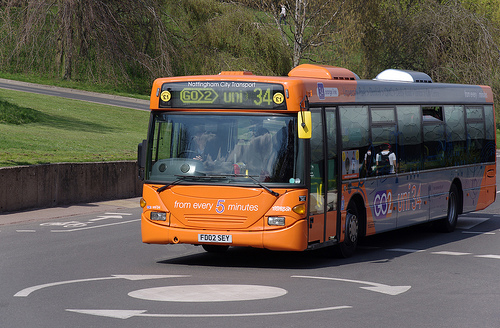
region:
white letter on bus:
[173, 198, 178, 210]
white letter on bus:
[177, 200, 184, 207]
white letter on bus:
[182, 200, 191, 209]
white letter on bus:
[191, 200, 198, 211]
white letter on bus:
[194, 199, 201, 208]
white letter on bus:
[200, 200, 206, 208]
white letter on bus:
[226, 200, 233, 211]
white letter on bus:
[373, 192, 383, 217]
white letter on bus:
[381, 192, 388, 215]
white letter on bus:
[252, 201, 259, 213]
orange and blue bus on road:
[129, 47, 499, 256]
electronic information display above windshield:
[115, 65, 295, 113]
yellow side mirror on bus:
[296, 92, 322, 138]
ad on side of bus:
[361, 158, 486, 243]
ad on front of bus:
[166, 190, 265, 217]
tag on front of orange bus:
[194, 224, 235, 251]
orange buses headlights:
[145, 197, 291, 232]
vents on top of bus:
[276, 46, 441, 88]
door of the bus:
[299, 96, 356, 249]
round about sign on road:
[24, 219, 421, 326]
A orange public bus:
[121, 49, 499, 266]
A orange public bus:
[133, 61, 498, 270]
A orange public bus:
[125, 54, 499, 269]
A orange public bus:
[123, 51, 494, 271]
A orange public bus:
[128, 59, 497, 261]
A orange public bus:
[131, 57, 499, 267]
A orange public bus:
[134, 60, 497, 260]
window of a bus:
[139, 105, 305, 195]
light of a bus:
[132, 190, 172, 241]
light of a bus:
[266, 205, 298, 238]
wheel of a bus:
[335, 195, 369, 253]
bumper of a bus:
[119, 180, 319, 260]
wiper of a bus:
[139, 163, 201, 210]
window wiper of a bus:
[238, 161, 311, 207]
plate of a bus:
[196, 225, 229, 247]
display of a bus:
[152, 81, 279, 113]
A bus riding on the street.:
[124, 58, 471, 256]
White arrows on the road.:
[301, 266, 411, 310]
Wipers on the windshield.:
[161, 167, 283, 197]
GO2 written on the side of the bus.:
[361, 174, 407, 222]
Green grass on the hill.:
[10, 89, 135, 146]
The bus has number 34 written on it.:
[244, 90, 279, 117]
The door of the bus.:
[300, 117, 346, 253]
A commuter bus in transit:
[136, 64, 497, 256]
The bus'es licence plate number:
[200, 233, 230, 244]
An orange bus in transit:
[135, 68, 497, 252]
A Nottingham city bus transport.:
[0, 0, 498, 326]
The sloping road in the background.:
[0, 79, 149, 121]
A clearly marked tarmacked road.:
[1, 154, 498, 326]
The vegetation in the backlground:
[1, 0, 498, 130]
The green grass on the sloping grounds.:
[0, 88, 150, 167]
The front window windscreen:
[146, 111, 296, 184]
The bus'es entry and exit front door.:
[303, 104, 340, 245]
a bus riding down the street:
[141, 64, 498, 253]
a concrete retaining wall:
[0, 159, 142, 216]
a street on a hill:
[1, 74, 159, 120]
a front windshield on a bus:
[148, 109, 295, 184]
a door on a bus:
[309, 105, 341, 245]